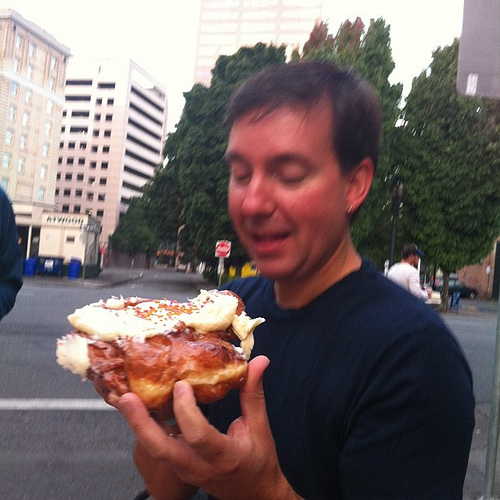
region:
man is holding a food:
[75, 272, 263, 425]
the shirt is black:
[179, 247, 424, 496]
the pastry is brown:
[56, 289, 261, 412]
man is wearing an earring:
[333, 176, 372, 245]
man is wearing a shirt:
[190, 263, 457, 497]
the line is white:
[11, 380, 89, 420]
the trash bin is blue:
[27, 242, 104, 285]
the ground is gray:
[18, 290, 49, 385]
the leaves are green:
[423, 173, 467, 271]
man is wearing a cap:
[388, 236, 455, 287]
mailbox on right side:
[449, 285, 465, 316]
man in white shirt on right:
[391, 244, 435, 307]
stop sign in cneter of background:
[209, 231, 229, 281]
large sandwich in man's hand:
[55, 282, 261, 465]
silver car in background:
[171, 255, 195, 278]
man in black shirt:
[160, 59, 475, 499]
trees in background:
[122, 34, 492, 282]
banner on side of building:
[122, 65, 160, 96]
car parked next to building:
[432, 274, 474, 303]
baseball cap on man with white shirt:
[400, 244, 420, 264]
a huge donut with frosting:
[40, 263, 286, 429]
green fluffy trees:
[112, 42, 465, 278]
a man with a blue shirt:
[165, 37, 480, 474]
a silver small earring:
[322, 192, 369, 221]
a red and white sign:
[195, 215, 250, 294]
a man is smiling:
[149, 45, 430, 257]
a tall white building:
[35, 44, 168, 285]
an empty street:
[116, 223, 207, 293]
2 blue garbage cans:
[0, 245, 85, 277]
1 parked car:
[405, 265, 475, 305]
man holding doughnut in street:
[128, 57, 463, 498]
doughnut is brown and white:
[32, 275, 280, 417]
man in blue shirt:
[121, 41, 478, 498]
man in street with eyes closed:
[132, 39, 490, 498]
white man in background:
[375, 233, 446, 299]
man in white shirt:
[382, 231, 425, 298]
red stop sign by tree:
[202, 238, 234, 277]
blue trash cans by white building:
[21, 251, 86, 279]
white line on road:
[14, 366, 149, 432]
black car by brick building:
[440, 274, 469, 303]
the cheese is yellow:
[52, 263, 253, 345]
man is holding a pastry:
[48, 252, 287, 469]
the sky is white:
[159, 72, 191, 131]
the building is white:
[64, 62, 174, 287]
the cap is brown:
[396, 235, 438, 260]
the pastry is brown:
[48, 285, 345, 460]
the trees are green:
[165, 149, 220, 253]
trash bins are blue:
[24, 249, 85, 285]